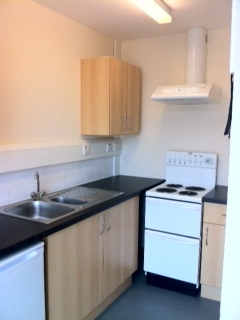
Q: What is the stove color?
A: White.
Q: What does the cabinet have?
A: Two doors.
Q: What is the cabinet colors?
A: Light brown.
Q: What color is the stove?
A: White.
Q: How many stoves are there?
A: One.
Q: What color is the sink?
A: Silver.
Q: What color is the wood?
A: Brown.